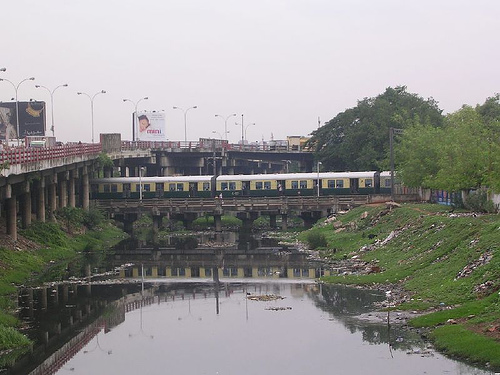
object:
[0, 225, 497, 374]
water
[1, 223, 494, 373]
murky water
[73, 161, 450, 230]
train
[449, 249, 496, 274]
trash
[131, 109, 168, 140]
billboard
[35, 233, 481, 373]
river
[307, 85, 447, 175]
trees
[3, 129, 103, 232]
structure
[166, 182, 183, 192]
window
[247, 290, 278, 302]
dirt&plastic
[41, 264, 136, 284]
dirt&plastic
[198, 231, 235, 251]
dirt&plastic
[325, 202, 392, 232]
garbage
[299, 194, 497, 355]
river banks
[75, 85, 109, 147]
light pole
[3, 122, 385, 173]
overpass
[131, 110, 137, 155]
pole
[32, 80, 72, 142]
light pole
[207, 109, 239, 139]
street light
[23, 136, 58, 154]
truck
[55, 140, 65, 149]
car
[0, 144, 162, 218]
over-pass highway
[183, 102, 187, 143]
pole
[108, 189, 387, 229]
track